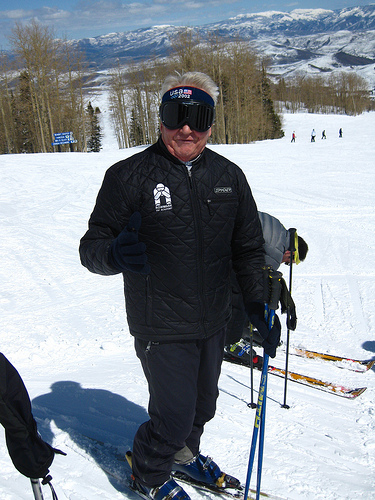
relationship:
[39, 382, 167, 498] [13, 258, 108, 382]
tracks in snow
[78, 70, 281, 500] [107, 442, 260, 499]
human wears skies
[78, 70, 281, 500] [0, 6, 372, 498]
human on snow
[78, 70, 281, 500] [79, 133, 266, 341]
human wears coat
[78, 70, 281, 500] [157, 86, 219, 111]
human wears headband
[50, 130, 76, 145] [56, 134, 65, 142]
sign with lettering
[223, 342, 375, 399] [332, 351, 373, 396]
skis has front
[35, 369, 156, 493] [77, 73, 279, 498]
shadow of a human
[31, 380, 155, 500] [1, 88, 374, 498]
shadow cast on snow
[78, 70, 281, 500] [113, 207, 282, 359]
human wearing gloves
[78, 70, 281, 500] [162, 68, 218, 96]
human has gray hair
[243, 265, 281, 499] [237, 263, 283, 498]
poles in pair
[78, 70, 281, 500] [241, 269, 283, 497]
human holding poles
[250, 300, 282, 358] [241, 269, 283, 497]
hand holding poles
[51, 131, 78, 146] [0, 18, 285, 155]
sign near trees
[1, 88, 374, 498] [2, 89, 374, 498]
snow on ground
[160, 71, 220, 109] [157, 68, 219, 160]
gray hair part of head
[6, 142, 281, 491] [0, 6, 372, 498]
ground covered in snow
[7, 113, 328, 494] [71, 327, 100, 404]
ground covered in snow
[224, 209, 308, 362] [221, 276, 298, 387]
person bending at knee